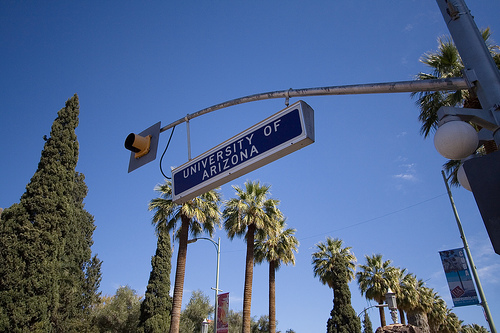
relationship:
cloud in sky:
[361, 143, 420, 187] [144, 66, 438, 205]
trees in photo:
[172, 201, 443, 321] [38, 24, 495, 315]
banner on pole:
[428, 244, 481, 310] [433, 174, 499, 325]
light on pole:
[123, 120, 158, 174] [177, 82, 488, 128]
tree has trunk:
[236, 197, 269, 318] [235, 233, 263, 330]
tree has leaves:
[236, 197, 269, 318] [230, 204, 265, 229]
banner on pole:
[214, 292, 232, 332] [210, 238, 235, 325]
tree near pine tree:
[224, 177, 276, 332] [141, 206, 179, 324]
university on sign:
[173, 134, 258, 159] [162, 130, 324, 189]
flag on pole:
[428, 244, 481, 310] [433, 174, 499, 325]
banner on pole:
[214, 292, 232, 332] [214, 238, 220, 332]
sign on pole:
[162, 130, 324, 189] [177, 82, 488, 128]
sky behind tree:
[144, 66, 438, 205] [224, 177, 276, 332]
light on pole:
[113, 121, 171, 180] [177, 82, 488, 128]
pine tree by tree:
[141, 206, 179, 324] [224, 177, 276, 332]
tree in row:
[224, 177, 276, 332] [173, 269, 393, 304]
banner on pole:
[199, 278, 249, 332] [210, 238, 235, 325]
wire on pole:
[163, 122, 176, 181] [177, 82, 488, 128]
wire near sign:
[163, 122, 176, 181] [162, 130, 324, 189]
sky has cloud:
[144, 66, 438, 205] [361, 143, 420, 187]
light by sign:
[123, 120, 158, 174] [162, 130, 324, 189]